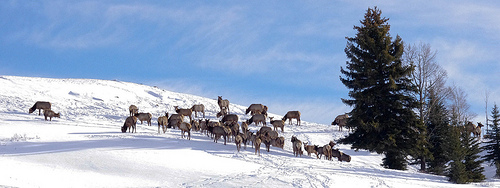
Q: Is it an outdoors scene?
A: Yes, it is outdoors.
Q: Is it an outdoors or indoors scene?
A: It is outdoors.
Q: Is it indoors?
A: No, it is outdoors.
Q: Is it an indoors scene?
A: No, it is outdoors.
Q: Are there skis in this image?
A: No, there are no skis.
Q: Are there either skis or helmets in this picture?
A: No, there are no skis or helmets.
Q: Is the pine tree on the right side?
A: Yes, the pine tree is on the right of the image.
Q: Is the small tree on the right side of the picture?
A: Yes, the pine tree is on the right of the image.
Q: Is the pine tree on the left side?
A: No, the pine tree is on the right of the image.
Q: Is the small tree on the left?
A: No, the pine tree is on the right of the image.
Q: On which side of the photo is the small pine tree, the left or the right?
A: The pine tree is on the right of the image.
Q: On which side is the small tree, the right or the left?
A: The pine tree is on the right of the image.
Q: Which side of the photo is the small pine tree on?
A: The pine tree is on the right of the image.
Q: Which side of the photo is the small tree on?
A: The pine tree is on the right of the image.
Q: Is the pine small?
A: Yes, the pine is small.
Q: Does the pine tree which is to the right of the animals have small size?
A: Yes, the pine tree is small.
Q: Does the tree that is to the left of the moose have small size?
A: Yes, the pine tree is small.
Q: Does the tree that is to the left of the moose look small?
A: Yes, the pine tree is small.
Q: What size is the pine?
A: The pine is small.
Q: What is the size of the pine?
A: The pine is small.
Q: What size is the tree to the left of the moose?
A: The pine is small.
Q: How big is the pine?
A: The pine is small.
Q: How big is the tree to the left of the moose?
A: The pine is small.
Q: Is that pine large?
A: No, the pine is small.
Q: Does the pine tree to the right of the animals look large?
A: No, the pine is small.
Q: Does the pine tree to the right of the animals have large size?
A: No, the pine is small.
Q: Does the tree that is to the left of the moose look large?
A: No, the pine is small.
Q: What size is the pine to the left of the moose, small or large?
A: The pine tree is small.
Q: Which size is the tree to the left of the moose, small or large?
A: The pine tree is small.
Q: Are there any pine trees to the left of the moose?
A: Yes, there is a pine tree to the left of the moose.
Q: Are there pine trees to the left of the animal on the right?
A: Yes, there is a pine tree to the left of the moose.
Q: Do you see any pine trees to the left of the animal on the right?
A: Yes, there is a pine tree to the left of the moose.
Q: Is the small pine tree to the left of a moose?
A: Yes, the pine is to the left of a moose.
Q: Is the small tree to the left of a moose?
A: Yes, the pine is to the left of a moose.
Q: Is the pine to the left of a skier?
A: No, the pine is to the left of a moose.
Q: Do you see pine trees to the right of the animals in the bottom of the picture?
A: Yes, there is a pine tree to the right of the animals.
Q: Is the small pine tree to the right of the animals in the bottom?
A: Yes, the pine is to the right of the animals.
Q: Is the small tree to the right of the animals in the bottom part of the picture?
A: Yes, the pine is to the right of the animals.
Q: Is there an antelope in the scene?
A: Yes, there is an antelope.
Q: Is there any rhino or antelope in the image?
A: Yes, there is an antelope.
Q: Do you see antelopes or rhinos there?
A: Yes, there is an antelope.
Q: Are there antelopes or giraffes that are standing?
A: Yes, the antelope is standing.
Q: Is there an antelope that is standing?
A: Yes, there is an antelope that is standing.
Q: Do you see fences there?
A: No, there are no fences.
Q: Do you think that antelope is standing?
A: Yes, the antelope is standing.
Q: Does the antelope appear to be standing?
A: Yes, the antelope is standing.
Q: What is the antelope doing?
A: The antelope is standing.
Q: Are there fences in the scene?
A: No, there are no fences.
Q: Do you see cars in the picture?
A: No, there are no cars.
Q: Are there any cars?
A: No, there are no cars.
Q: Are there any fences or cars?
A: No, there are no cars or fences.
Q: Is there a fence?
A: No, there are no fences.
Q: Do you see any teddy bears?
A: No, there are no teddy bears.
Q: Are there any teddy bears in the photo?
A: No, there are no teddy bears.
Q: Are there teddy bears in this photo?
A: No, there are no teddy bears.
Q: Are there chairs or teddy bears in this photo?
A: No, there are no teddy bears or chairs.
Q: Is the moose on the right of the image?
A: Yes, the moose is on the right of the image.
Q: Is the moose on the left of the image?
A: No, the moose is on the right of the image.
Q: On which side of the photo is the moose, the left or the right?
A: The moose is on the right of the image.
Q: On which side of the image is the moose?
A: The moose is on the right of the image.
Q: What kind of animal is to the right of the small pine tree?
A: The animal is a moose.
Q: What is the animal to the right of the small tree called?
A: The animal is a moose.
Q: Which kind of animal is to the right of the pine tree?
A: The animal is a moose.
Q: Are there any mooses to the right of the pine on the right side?
A: Yes, there is a moose to the right of the pine.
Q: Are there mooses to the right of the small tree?
A: Yes, there is a moose to the right of the pine.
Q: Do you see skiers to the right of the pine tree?
A: No, there is a moose to the right of the pine tree.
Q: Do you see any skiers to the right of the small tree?
A: No, there is a moose to the right of the pine tree.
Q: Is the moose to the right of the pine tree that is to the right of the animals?
A: Yes, the moose is to the right of the pine.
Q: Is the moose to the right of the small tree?
A: Yes, the moose is to the right of the pine.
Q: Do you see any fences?
A: No, there are no fences.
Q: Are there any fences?
A: No, there are no fences.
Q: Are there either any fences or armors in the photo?
A: No, there are no fences or armors.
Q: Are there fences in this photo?
A: No, there are no fences.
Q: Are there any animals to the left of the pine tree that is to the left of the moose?
A: Yes, there are animals to the left of the pine tree.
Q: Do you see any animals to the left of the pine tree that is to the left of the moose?
A: Yes, there are animals to the left of the pine tree.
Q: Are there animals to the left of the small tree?
A: Yes, there are animals to the left of the pine tree.